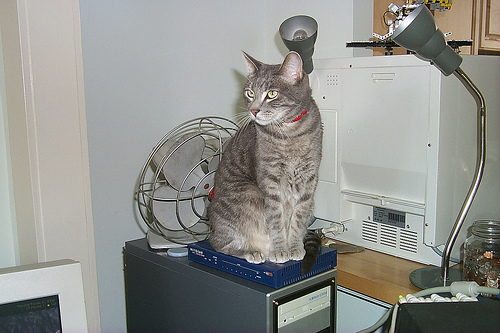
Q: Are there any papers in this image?
A: No, there are no papers.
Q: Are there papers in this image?
A: No, there are no papers.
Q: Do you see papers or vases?
A: No, there are no papers or vases.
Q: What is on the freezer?
A: The figure is on the freezer.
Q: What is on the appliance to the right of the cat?
A: The figure is on the freezer.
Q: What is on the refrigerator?
A: The figure is on the freezer.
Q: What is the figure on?
A: The figure is on the refrigerator.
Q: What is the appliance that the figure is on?
A: The appliance is a refrigerator.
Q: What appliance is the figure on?
A: The figure is on the fridge.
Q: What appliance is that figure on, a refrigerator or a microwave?
A: The figure is on a refrigerator.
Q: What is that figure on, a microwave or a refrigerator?
A: The figure is on a refrigerator.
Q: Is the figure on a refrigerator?
A: Yes, the figure is on a refrigerator.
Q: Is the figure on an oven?
A: No, the figure is on a refrigerator.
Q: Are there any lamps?
A: Yes, there is a lamp.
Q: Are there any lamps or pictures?
A: Yes, there is a lamp.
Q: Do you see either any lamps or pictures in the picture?
A: Yes, there is a lamp.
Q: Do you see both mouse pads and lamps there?
A: No, there is a lamp but no mouse pads.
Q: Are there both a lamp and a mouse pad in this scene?
A: No, there is a lamp but no mouse pads.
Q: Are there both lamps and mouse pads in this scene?
A: No, there is a lamp but no mouse pads.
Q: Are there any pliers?
A: No, there are no pliers.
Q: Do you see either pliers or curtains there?
A: No, there are no pliers or curtains.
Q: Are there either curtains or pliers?
A: No, there are no pliers or curtains.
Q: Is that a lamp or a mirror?
A: That is a lamp.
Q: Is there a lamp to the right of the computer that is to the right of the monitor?
A: Yes, there is a lamp to the right of the computer.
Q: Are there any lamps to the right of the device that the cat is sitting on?
A: Yes, there is a lamp to the right of the computer.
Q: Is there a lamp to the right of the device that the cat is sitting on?
A: Yes, there is a lamp to the right of the computer.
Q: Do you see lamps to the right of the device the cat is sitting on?
A: Yes, there is a lamp to the right of the computer.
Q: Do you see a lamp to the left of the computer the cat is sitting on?
A: No, the lamp is to the right of the computer.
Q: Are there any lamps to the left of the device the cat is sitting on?
A: No, the lamp is to the right of the computer.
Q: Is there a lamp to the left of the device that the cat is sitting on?
A: No, the lamp is to the right of the computer.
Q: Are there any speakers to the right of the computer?
A: No, there is a lamp to the right of the computer.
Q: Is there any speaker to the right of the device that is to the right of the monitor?
A: No, there is a lamp to the right of the computer.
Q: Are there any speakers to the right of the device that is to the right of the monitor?
A: No, there is a lamp to the right of the computer.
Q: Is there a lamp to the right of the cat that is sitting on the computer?
A: Yes, there is a lamp to the right of the cat.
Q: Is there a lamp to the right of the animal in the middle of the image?
A: Yes, there is a lamp to the right of the cat.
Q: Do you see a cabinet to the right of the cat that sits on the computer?
A: No, there is a lamp to the right of the cat.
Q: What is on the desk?
A: The lamp is on the desk.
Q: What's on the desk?
A: The lamp is on the desk.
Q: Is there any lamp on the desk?
A: Yes, there is a lamp on the desk.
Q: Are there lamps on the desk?
A: Yes, there is a lamp on the desk.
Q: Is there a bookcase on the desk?
A: No, there is a lamp on the desk.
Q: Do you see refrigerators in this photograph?
A: Yes, there is a refrigerator.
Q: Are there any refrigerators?
A: Yes, there is a refrigerator.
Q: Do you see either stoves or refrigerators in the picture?
A: Yes, there is a refrigerator.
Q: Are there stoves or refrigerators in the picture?
A: Yes, there is a refrigerator.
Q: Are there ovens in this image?
A: No, there are no ovens.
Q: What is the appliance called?
A: The appliance is a refrigerator.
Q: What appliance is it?
A: The appliance is a refrigerator.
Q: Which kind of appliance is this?
A: That is a refrigerator.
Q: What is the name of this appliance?
A: That is a refrigerator.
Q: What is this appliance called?
A: That is a refrigerator.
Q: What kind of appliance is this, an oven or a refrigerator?
A: That is a refrigerator.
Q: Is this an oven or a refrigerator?
A: This is a refrigerator.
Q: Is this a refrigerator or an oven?
A: This is a refrigerator.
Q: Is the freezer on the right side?
A: Yes, the freezer is on the right of the image.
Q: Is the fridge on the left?
A: No, the fridge is on the right of the image.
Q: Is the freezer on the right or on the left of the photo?
A: The freezer is on the right of the image.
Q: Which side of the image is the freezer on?
A: The freezer is on the right of the image.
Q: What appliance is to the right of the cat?
A: The appliance is a refrigerator.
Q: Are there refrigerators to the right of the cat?
A: Yes, there is a refrigerator to the right of the cat.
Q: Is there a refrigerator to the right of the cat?
A: Yes, there is a refrigerator to the right of the cat.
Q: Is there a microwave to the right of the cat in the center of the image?
A: No, there is a refrigerator to the right of the cat.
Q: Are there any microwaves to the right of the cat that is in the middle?
A: No, there is a refrigerator to the right of the cat.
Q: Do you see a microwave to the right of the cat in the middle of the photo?
A: No, there is a refrigerator to the right of the cat.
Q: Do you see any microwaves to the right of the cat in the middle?
A: No, there is a refrigerator to the right of the cat.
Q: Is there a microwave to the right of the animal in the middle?
A: No, there is a refrigerator to the right of the cat.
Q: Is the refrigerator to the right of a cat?
A: Yes, the refrigerator is to the right of a cat.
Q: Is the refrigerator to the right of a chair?
A: No, the refrigerator is to the right of a cat.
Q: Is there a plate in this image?
A: Yes, there is a plate.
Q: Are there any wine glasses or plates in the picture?
A: Yes, there is a plate.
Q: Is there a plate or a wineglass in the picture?
A: Yes, there is a plate.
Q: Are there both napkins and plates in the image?
A: No, there is a plate but no napkins.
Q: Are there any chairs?
A: No, there are no chairs.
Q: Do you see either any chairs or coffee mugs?
A: No, there are no chairs or coffee mugs.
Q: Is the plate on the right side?
A: Yes, the plate is on the right of the image.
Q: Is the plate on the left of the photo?
A: No, the plate is on the right of the image.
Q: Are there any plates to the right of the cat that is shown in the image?
A: Yes, there is a plate to the right of the cat.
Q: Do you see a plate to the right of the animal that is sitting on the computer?
A: Yes, there is a plate to the right of the cat.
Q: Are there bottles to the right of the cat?
A: No, there is a plate to the right of the cat.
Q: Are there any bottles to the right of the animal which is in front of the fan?
A: No, there is a plate to the right of the cat.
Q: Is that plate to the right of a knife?
A: No, the plate is to the right of the cat.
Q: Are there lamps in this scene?
A: Yes, there is a lamp.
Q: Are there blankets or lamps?
A: Yes, there is a lamp.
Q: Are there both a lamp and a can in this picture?
A: No, there is a lamp but no cans.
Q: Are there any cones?
A: No, there are no cones.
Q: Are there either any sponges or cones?
A: No, there are no cones or sponges.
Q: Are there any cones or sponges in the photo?
A: No, there are no cones or sponges.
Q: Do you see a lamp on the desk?
A: Yes, there is a lamp on the desk.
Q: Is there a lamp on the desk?
A: Yes, there is a lamp on the desk.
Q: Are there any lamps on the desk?
A: Yes, there is a lamp on the desk.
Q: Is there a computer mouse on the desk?
A: No, there is a lamp on the desk.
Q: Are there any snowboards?
A: No, there are no snowboards.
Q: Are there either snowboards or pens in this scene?
A: No, there are no snowboards or pens.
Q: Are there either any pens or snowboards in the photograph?
A: No, there are no snowboards or pens.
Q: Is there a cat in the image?
A: Yes, there is a cat.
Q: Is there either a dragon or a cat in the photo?
A: Yes, there is a cat.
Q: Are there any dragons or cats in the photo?
A: Yes, there is a cat.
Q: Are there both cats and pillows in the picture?
A: No, there is a cat but no pillows.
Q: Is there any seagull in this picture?
A: No, there are no seagulls.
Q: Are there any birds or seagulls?
A: No, there are no seagulls or birds.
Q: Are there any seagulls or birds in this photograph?
A: No, there are no seagulls or birds.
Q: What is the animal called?
A: The animal is a cat.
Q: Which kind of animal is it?
A: The animal is a cat.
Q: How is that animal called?
A: That is a cat.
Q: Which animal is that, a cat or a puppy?
A: That is a cat.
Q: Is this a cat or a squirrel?
A: This is a cat.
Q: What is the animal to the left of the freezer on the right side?
A: The animal is a cat.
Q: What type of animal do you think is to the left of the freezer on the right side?
A: The animal is a cat.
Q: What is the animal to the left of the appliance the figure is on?
A: The animal is a cat.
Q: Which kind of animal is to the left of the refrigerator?
A: The animal is a cat.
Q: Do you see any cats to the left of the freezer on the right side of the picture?
A: Yes, there is a cat to the left of the freezer.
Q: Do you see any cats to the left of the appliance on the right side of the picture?
A: Yes, there is a cat to the left of the freezer.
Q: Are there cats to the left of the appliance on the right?
A: Yes, there is a cat to the left of the freezer.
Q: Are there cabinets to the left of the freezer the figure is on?
A: No, there is a cat to the left of the refrigerator.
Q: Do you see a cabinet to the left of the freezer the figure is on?
A: No, there is a cat to the left of the refrigerator.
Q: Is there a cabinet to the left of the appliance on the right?
A: No, there is a cat to the left of the refrigerator.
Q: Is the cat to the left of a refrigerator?
A: Yes, the cat is to the left of a refrigerator.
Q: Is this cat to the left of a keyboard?
A: No, the cat is to the left of a refrigerator.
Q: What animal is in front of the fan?
A: The cat is in front of the fan.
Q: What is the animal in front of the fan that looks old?
A: The animal is a cat.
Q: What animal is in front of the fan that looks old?
A: The animal is a cat.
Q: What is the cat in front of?
A: The cat is in front of the fan.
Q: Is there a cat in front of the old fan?
A: Yes, there is a cat in front of the fan.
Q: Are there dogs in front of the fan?
A: No, there is a cat in front of the fan.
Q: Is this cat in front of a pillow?
A: No, the cat is in front of the fan.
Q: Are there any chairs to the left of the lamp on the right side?
A: No, there is a cat to the left of the lamp.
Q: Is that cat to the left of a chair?
A: No, the cat is to the left of the lamp.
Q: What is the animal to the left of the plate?
A: The animal is a cat.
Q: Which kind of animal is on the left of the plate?
A: The animal is a cat.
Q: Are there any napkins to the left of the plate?
A: No, there is a cat to the left of the plate.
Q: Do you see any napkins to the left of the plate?
A: No, there is a cat to the left of the plate.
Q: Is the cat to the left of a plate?
A: Yes, the cat is to the left of a plate.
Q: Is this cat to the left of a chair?
A: No, the cat is to the left of a plate.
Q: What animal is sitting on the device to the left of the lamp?
A: The cat is sitting on the computer.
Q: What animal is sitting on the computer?
A: The cat is sitting on the computer.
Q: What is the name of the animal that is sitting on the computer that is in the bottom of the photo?
A: The animal is a cat.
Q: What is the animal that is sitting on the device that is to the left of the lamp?
A: The animal is a cat.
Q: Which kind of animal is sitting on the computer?
A: The animal is a cat.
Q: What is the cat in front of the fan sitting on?
A: The cat is sitting on the computer.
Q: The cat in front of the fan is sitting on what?
A: The cat is sitting on the computer.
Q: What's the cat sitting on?
A: The cat is sitting on the computer.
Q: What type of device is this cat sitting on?
A: The cat is sitting on the computer.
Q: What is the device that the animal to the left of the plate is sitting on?
A: The device is a computer.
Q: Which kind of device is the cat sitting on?
A: The cat is sitting on the computer.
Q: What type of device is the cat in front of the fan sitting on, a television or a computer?
A: The cat is sitting on a computer.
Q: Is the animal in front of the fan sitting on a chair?
A: No, the cat is sitting on the computer.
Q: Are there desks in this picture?
A: Yes, there is a desk.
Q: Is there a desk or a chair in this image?
A: Yes, there is a desk.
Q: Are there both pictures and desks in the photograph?
A: No, there is a desk but no pictures.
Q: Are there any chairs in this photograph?
A: No, there are no chairs.